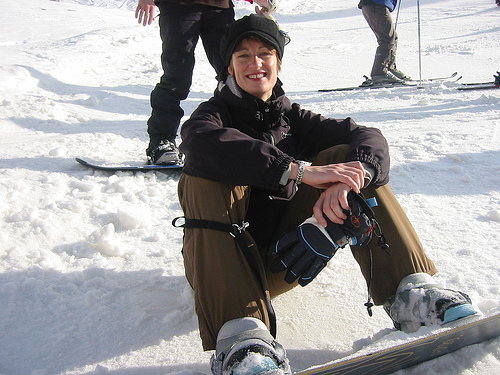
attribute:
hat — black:
[200, 4, 307, 80]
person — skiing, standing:
[298, 2, 474, 112]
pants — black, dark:
[121, 1, 263, 171]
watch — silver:
[282, 152, 313, 195]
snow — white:
[1, 128, 299, 371]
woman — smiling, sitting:
[167, 14, 400, 371]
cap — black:
[204, 7, 315, 122]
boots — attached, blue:
[192, 274, 486, 374]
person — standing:
[124, 0, 293, 173]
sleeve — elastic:
[164, 99, 407, 207]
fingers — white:
[285, 152, 377, 232]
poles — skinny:
[385, 1, 439, 90]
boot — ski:
[186, 304, 332, 373]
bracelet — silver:
[283, 143, 313, 191]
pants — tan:
[336, 2, 416, 98]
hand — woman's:
[307, 181, 354, 229]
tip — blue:
[441, 300, 476, 326]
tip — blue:
[234, 354, 280, 372]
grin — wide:
[241, 69, 272, 84]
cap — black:
[216, 14, 294, 61]